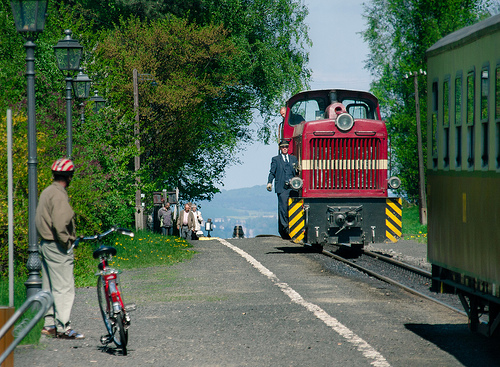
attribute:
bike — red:
[78, 223, 140, 363]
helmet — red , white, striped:
[47, 155, 78, 175]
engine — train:
[261, 85, 399, 253]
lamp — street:
[8, 4, 46, 46]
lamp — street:
[69, 68, 100, 105]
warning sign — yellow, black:
[285, 198, 309, 242]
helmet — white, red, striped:
[44, 154, 83, 174]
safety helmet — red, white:
[48, 148, 90, 179]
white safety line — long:
[216, 234, 382, 365]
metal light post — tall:
[7, 6, 74, 326]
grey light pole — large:
[53, 30, 120, 218]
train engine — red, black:
[247, 79, 417, 260]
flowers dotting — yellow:
[100, 226, 194, 270]